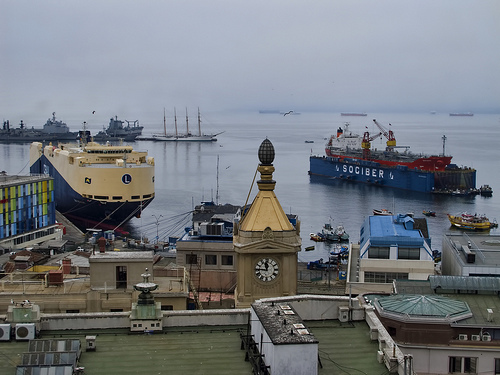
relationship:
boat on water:
[308, 119, 494, 195] [0, 104, 499, 264]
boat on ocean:
[138, 89, 229, 153] [5, 98, 498, 226]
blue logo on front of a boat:
[120, 167, 135, 189] [29, 121, 155, 225]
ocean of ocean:
[0, 113, 499, 262] [4, 143, 497, 198]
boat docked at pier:
[29, 121, 155, 225] [7, 110, 482, 292]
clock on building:
[254, 258, 278, 282] [231, 135, 302, 309]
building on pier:
[231, 135, 302, 309] [52, 203, 90, 245]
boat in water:
[308, 119, 494, 195] [1, 113, 499, 277]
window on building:
[369, 246, 389, 258] [342, 212, 435, 293]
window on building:
[396, 244, 421, 259] [342, 212, 435, 293]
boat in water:
[298, 120, 489, 205] [148, 118, 497, 242]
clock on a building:
[254, 258, 278, 282] [220, 112, 318, 319]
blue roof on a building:
[358, 210, 424, 247] [357, 213, 440, 283]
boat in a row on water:
[308, 119, 494, 195] [244, 110, 285, 149]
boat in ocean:
[308, 119, 494, 195] [2, 105, 496, 264]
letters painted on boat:
[337, 161, 386, 178] [297, 143, 492, 198]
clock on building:
[254, 258, 278, 282] [221, 125, 311, 309]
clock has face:
[255, 257, 280, 282] [250, 256, 280, 284]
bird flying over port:
[229, 97, 310, 137] [0, 112, 498, 372]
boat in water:
[25, 136, 156, 236] [0, 104, 499, 264]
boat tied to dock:
[29, 121, 155, 225] [3, 232, 143, 285]